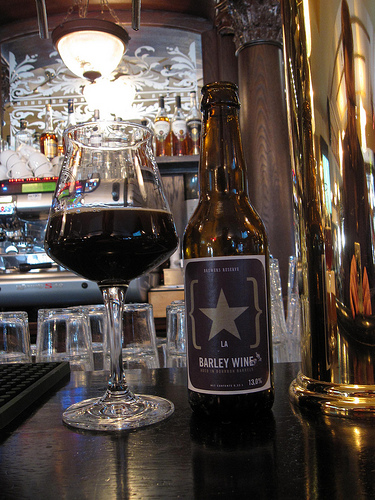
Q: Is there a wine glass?
A: Yes, there is a wine glass.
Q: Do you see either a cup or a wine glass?
A: Yes, there is a wine glass.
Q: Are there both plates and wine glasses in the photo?
A: No, there is a wine glass but no plates.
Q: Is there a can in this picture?
A: No, there are no cans.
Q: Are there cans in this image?
A: No, there are no cans.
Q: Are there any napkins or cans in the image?
A: No, there are no cans or napkins.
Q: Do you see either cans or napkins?
A: No, there are no cans or napkins.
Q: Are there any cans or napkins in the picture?
A: No, there are no cans or napkins.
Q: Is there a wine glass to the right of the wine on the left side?
A: Yes, there is a wine glass to the right of the wine.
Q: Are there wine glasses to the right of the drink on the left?
A: Yes, there is a wine glass to the right of the wine.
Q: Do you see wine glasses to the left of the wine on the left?
A: No, the wine glass is to the right of the wine.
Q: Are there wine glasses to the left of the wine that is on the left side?
A: No, the wine glass is to the right of the wine.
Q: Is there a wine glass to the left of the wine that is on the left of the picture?
A: No, the wine glass is to the right of the wine.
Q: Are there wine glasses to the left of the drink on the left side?
A: No, the wine glass is to the right of the wine.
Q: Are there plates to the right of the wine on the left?
A: No, there is a wine glass to the right of the wine.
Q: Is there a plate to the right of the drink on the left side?
A: No, there is a wine glass to the right of the wine.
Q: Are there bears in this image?
A: Yes, there is a bear.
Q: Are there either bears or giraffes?
A: Yes, there is a bear.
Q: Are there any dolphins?
A: No, there are no dolphins.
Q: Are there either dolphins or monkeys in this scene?
A: No, there are no dolphins or monkeys.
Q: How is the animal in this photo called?
A: The animal is a bear.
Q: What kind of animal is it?
A: The animal is a bear.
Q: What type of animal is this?
A: This is a bear.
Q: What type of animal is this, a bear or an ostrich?
A: This is a bear.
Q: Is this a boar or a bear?
A: This is a bear.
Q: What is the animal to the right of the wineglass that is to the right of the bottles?
A: The animal is a bear.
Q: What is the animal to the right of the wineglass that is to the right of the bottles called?
A: The animal is a bear.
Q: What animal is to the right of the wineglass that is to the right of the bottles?
A: The animal is a bear.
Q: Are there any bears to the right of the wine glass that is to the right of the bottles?
A: Yes, there is a bear to the right of the wineglass.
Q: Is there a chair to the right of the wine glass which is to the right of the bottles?
A: No, there is a bear to the right of the wineglass.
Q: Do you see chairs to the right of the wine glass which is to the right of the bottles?
A: No, there is a bear to the right of the wineglass.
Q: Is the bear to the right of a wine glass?
A: Yes, the bear is to the right of a wine glass.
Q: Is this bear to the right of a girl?
A: No, the bear is to the right of a wine glass.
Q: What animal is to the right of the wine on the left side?
A: The animal is a bear.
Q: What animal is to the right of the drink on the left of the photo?
A: The animal is a bear.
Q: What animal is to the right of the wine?
A: The animal is a bear.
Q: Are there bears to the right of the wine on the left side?
A: Yes, there is a bear to the right of the wine.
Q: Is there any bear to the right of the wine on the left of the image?
A: Yes, there is a bear to the right of the wine.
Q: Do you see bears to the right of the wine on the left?
A: Yes, there is a bear to the right of the wine.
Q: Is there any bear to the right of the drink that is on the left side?
A: Yes, there is a bear to the right of the wine.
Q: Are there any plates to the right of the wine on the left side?
A: No, there is a bear to the right of the wine.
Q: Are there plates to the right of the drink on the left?
A: No, there is a bear to the right of the wine.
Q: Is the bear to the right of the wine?
A: Yes, the bear is to the right of the wine.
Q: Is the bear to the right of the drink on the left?
A: Yes, the bear is to the right of the wine.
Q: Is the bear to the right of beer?
A: No, the bear is to the right of the wine.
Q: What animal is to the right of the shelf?
A: The animal is a bear.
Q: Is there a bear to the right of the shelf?
A: Yes, there is a bear to the right of the shelf.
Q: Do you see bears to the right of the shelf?
A: Yes, there is a bear to the right of the shelf.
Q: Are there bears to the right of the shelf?
A: Yes, there is a bear to the right of the shelf.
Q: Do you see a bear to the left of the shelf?
A: No, the bear is to the right of the shelf.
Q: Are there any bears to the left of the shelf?
A: No, the bear is to the right of the shelf.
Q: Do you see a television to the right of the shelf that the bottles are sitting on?
A: No, there is a bear to the right of the shelf.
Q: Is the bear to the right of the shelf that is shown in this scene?
A: Yes, the bear is to the right of the shelf.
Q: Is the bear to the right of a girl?
A: No, the bear is to the right of the shelf.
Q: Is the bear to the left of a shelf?
A: No, the bear is to the right of a shelf.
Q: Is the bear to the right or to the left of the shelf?
A: The bear is to the right of the shelf.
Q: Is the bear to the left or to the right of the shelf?
A: The bear is to the right of the shelf.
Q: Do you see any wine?
A: Yes, there is wine.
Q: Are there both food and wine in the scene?
A: No, there is wine but no food.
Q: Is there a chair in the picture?
A: No, there are no chairs.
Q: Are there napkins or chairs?
A: No, there are no chairs or napkins.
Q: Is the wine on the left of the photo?
A: Yes, the wine is on the left of the image.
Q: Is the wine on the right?
A: No, the wine is on the left of the image.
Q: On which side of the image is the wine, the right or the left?
A: The wine is on the left of the image.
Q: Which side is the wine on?
A: The wine is on the left of the image.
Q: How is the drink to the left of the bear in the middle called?
A: The drink is wine.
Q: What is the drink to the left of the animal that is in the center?
A: The drink is wine.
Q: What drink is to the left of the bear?
A: The drink is wine.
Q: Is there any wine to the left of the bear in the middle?
A: Yes, there is wine to the left of the bear.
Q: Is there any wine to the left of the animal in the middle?
A: Yes, there is wine to the left of the bear.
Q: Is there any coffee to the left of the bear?
A: No, there is wine to the left of the bear.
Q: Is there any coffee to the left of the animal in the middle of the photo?
A: No, there is wine to the left of the bear.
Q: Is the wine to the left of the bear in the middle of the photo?
A: Yes, the wine is to the left of the bear.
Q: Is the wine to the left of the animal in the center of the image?
A: Yes, the wine is to the left of the bear.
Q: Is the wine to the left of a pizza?
A: No, the wine is to the left of the bear.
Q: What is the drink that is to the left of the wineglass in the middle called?
A: The drink is wine.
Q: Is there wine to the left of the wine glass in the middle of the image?
A: Yes, there is wine to the left of the wineglass.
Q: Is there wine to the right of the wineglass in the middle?
A: No, the wine is to the left of the wine glass.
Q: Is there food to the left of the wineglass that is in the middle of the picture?
A: No, there is wine to the left of the wine glass.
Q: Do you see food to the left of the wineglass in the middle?
A: No, there is wine to the left of the wine glass.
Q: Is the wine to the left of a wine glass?
A: Yes, the wine is to the left of a wine glass.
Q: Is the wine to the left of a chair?
A: No, the wine is to the left of a wine glass.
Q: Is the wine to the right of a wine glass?
A: No, the wine is to the left of a wine glass.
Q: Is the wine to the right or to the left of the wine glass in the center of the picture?
A: The wine is to the left of the wineglass.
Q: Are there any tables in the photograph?
A: Yes, there is a table.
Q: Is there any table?
A: Yes, there is a table.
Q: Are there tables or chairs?
A: Yes, there is a table.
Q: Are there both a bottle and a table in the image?
A: Yes, there are both a table and a bottle.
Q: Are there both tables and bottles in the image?
A: Yes, there are both a table and a bottle.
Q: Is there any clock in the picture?
A: No, there are no clocks.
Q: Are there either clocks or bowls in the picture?
A: No, there are no clocks or bowls.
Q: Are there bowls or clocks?
A: No, there are no clocks or bowls.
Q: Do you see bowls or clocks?
A: No, there are no clocks or bowls.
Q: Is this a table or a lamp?
A: This is a table.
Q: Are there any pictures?
A: No, there are no pictures.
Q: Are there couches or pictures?
A: No, there are no pictures or couches.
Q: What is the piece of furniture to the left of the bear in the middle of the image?
A: The piece of furniture is a shelf.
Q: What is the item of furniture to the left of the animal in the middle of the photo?
A: The piece of furniture is a shelf.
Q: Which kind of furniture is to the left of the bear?
A: The piece of furniture is a shelf.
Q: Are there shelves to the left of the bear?
A: Yes, there is a shelf to the left of the bear.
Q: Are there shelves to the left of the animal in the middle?
A: Yes, there is a shelf to the left of the bear.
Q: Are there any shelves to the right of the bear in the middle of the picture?
A: No, the shelf is to the left of the bear.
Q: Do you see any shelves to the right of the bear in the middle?
A: No, the shelf is to the left of the bear.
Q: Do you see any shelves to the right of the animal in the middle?
A: No, the shelf is to the left of the bear.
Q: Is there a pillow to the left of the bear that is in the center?
A: No, there is a shelf to the left of the bear.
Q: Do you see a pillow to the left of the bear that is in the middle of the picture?
A: No, there is a shelf to the left of the bear.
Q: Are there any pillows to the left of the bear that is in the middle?
A: No, there is a shelf to the left of the bear.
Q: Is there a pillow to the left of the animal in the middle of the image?
A: No, there is a shelf to the left of the bear.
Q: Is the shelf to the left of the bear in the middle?
A: Yes, the shelf is to the left of the bear.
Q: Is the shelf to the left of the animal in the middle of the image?
A: Yes, the shelf is to the left of the bear.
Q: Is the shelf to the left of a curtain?
A: No, the shelf is to the left of the bear.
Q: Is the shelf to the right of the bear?
A: No, the shelf is to the left of the bear.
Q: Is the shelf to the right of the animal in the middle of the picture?
A: No, the shelf is to the left of the bear.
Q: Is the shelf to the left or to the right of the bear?
A: The shelf is to the left of the bear.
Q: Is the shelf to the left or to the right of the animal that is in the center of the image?
A: The shelf is to the left of the bear.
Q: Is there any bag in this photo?
A: No, there are no bags.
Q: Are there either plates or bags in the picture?
A: No, there are no bags or plates.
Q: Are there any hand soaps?
A: No, there are no hand soaps.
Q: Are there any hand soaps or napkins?
A: No, there are no hand soaps or napkins.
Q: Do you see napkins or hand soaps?
A: No, there are no hand soaps or napkins.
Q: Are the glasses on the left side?
A: Yes, the glasses are on the left of the image.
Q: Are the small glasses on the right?
A: No, the glasses are on the left of the image.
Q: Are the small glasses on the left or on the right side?
A: The glasses are on the left of the image.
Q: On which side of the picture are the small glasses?
A: The glasses are on the left of the image.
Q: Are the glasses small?
A: Yes, the glasses are small.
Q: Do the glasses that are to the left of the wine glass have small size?
A: Yes, the glasses are small.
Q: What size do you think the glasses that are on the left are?
A: The glasses are small.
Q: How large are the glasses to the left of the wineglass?
A: The glasses are small.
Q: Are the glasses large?
A: No, the glasses are small.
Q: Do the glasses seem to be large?
A: No, the glasses are small.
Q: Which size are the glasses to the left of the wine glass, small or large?
A: The glasses are small.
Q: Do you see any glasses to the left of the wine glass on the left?
A: Yes, there are glasses to the left of the wineglass.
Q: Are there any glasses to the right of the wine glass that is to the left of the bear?
A: No, the glasses are to the left of the wine glass.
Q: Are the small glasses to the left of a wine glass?
A: Yes, the glasses are to the left of a wine glass.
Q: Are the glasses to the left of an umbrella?
A: No, the glasses are to the left of a wine glass.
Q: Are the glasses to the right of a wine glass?
A: No, the glasses are to the left of a wine glass.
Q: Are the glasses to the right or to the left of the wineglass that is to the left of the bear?
A: The glasses are to the left of the wine glass.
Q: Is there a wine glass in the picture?
A: Yes, there is a wine glass.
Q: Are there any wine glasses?
A: Yes, there is a wine glass.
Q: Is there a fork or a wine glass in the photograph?
A: Yes, there is a wine glass.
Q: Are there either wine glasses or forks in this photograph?
A: Yes, there is a wine glass.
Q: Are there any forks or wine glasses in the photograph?
A: Yes, there is a wine glass.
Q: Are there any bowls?
A: No, there are no bowls.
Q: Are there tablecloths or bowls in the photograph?
A: No, there are no bowls or tablecloths.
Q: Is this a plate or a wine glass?
A: This is a wine glass.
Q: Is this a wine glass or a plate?
A: This is a wine glass.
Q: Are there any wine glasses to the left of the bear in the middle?
A: Yes, there is a wine glass to the left of the bear.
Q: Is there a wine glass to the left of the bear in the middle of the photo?
A: Yes, there is a wine glass to the left of the bear.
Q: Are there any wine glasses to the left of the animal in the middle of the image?
A: Yes, there is a wine glass to the left of the bear.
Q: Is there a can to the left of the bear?
A: No, there is a wine glass to the left of the bear.